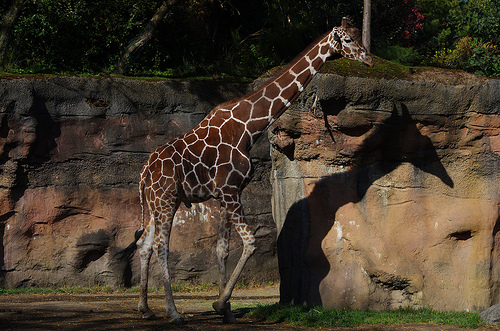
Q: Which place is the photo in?
A: It is at the zoo.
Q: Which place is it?
A: It is a zoo.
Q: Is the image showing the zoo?
A: Yes, it is showing the zoo.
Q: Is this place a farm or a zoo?
A: It is a zoo.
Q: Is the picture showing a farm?
A: No, the picture is showing a zoo.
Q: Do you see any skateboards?
A: No, there are no skateboards.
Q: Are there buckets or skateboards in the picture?
A: No, there are no skateboards or buckets.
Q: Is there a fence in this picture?
A: No, there are no fences.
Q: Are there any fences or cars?
A: No, there are no fences or cars.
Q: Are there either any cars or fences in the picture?
A: No, there are no fences or cars.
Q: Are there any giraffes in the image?
A: Yes, there is a giraffe.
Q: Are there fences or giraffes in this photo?
A: Yes, there is a giraffe.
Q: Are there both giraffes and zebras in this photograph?
A: No, there is a giraffe but no zebras.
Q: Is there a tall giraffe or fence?
A: Yes, there is a tall giraffe.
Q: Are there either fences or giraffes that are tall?
A: Yes, the giraffe is tall.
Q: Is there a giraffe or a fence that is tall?
A: Yes, the giraffe is tall.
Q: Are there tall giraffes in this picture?
A: Yes, there is a tall giraffe.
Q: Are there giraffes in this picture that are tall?
A: Yes, there is a giraffe that is tall.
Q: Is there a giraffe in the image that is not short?
A: Yes, there is a tall giraffe.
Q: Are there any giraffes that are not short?
A: Yes, there is a tall giraffe.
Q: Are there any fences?
A: No, there are no fences.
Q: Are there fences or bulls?
A: No, there are no fences or bulls.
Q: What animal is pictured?
A: The animal is a giraffe.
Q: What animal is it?
A: The animal is a giraffe.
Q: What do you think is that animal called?
A: That is a giraffe.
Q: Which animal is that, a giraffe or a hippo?
A: That is a giraffe.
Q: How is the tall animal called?
A: The animal is a giraffe.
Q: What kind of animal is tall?
A: The animal is a giraffe.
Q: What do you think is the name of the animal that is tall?
A: The animal is a giraffe.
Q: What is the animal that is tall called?
A: The animal is a giraffe.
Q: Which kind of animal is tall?
A: The animal is a giraffe.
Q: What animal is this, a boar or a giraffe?
A: This is a giraffe.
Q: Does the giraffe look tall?
A: Yes, the giraffe is tall.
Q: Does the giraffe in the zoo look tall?
A: Yes, the giraffe is tall.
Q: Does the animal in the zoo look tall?
A: Yes, the giraffe is tall.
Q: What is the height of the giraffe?
A: The giraffe is tall.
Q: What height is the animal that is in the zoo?
A: The giraffe is tall.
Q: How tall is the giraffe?
A: The giraffe is tall.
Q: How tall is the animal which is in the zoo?
A: The giraffe is tall.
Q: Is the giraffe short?
A: No, the giraffe is tall.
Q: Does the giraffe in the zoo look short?
A: No, the giraffe is tall.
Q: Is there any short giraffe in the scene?
A: No, there is a giraffe but it is tall.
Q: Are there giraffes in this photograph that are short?
A: No, there is a giraffe but it is tall.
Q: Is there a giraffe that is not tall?
A: No, there is a giraffe but it is tall.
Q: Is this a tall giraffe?
A: Yes, this is a tall giraffe.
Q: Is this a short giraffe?
A: No, this is a tall giraffe.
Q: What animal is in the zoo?
A: The giraffe is in the zoo.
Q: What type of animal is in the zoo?
A: The animal is a giraffe.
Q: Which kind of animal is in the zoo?
A: The animal is a giraffe.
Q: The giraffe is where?
A: The giraffe is in the zoo.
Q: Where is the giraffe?
A: The giraffe is in the zoo.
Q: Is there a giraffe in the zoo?
A: Yes, there is a giraffe in the zoo.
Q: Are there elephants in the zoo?
A: No, there is a giraffe in the zoo.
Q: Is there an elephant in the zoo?
A: No, there is a giraffe in the zoo.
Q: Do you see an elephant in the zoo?
A: No, there is a giraffe in the zoo.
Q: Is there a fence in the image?
A: No, there are no fences.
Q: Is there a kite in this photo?
A: No, there are no kites.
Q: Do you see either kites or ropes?
A: No, there are no kites or ropes.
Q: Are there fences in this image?
A: No, there are no fences.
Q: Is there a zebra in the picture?
A: No, there are no zebras.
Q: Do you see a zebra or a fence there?
A: No, there are no zebras or fences.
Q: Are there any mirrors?
A: No, there are no mirrors.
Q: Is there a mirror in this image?
A: No, there are no mirrors.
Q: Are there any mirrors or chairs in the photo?
A: No, there are no mirrors or chairs.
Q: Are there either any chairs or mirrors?
A: No, there are no mirrors or chairs.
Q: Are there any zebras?
A: No, there are no zebras.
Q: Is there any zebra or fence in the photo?
A: No, there are no zebras or fences.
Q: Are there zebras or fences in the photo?
A: No, there are no zebras or fences.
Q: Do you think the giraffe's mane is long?
A: Yes, the mane is long.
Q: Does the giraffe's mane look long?
A: Yes, the mane is long.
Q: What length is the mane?
A: The mane is long.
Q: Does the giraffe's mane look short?
A: No, the mane is long.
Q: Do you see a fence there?
A: No, there are no fences.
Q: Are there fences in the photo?
A: No, there are no fences.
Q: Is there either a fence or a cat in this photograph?
A: No, there are no fences or cats.